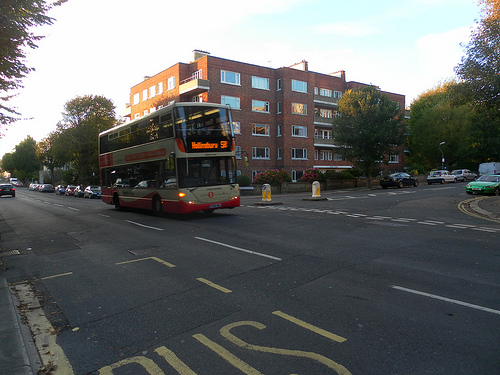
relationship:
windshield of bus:
[180, 149, 244, 188] [98, 98, 249, 220]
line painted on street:
[188, 232, 283, 267] [5, 179, 499, 371]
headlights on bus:
[177, 188, 199, 205] [98, 98, 249, 220]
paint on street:
[219, 327, 235, 335] [5, 179, 499, 371]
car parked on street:
[456, 168, 498, 204] [5, 179, 499, 371]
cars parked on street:
[24, 178, 105, 200] [5, 179, 499, 371]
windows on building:
[218, 70, 270, 118] [122, 51, 406, 194]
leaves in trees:
[436, 105, 450, 115] [409, 13, 498, 167]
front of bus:
[167, 101, 245, 207] [98, 98, 249, 220]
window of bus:
[172, 105, 232, 141] [98, 98, 249, 220]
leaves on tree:
[436, 105, 450, 115] [408, 86, 475, 170]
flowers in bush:
[253, 173, 269, 183] [254, 169, 294, 185]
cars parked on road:
[24, 178, 105, 200] [5, 179, 499, 371]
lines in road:
[99, 211, 344, 345] [5, 179, 499, 371]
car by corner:
[456, 168, 498, 204] [463, 194, 499, 226]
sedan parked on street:
[451, 165, 475, 181] [5, 179, 499, 371]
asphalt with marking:
[5, 179, 499, 371] [99, 211, 344, 345]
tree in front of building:
[324, 79, 408, 201] [122, 51, 406, 194]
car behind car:
[423, 170, 456, 188] [375, 170, 422, 189]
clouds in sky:
[306, 16, 438, 77] [0, 4, 456, 134]